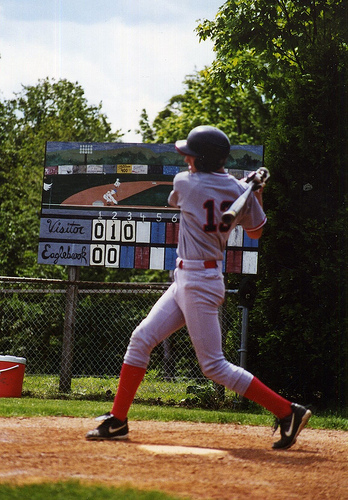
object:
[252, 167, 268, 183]
handle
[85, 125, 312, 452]
boy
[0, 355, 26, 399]
plate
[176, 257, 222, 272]
belt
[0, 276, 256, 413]
fence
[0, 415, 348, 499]
ground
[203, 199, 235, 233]
number 13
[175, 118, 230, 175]
helmet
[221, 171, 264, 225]
baseball bat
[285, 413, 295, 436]
nike swoosh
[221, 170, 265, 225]
bat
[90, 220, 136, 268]
numbers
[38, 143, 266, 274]
scoreboard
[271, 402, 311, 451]
shoe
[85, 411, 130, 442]
shoe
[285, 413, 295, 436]
logo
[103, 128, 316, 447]
baseball game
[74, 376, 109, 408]
grass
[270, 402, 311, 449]
baseball cleat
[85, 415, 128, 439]
baseball cleat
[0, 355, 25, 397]
cooler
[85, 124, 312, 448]
man